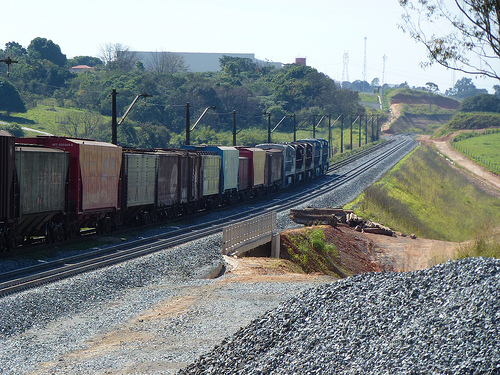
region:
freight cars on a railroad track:
[1, 131, 398, 242]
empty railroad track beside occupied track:
[0, 128, 413, 303]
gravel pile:
[174, 257, 499, 374]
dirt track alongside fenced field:
[428, 126, 498, 190]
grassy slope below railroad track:
[351, 139, 496, 238]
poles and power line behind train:
[4, 89, 330, 232]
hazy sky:
[1, 2, 499, 91]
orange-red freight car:
[19, 134, 121, 239]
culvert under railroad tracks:
[198, 208, 293, 264]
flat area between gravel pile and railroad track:
[1, 231, 498, 374]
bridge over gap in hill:
[210, 207, 285, 267]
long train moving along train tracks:
[0, 126, 332, 256]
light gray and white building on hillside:
[105, 45, 256, 90]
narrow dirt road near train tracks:
[425, 131, 495, 207]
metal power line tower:
[336, 45, 351, 100]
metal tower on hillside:
[376, 47, 386, 92]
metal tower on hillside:
[356, 26, 368, 91]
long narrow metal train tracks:
[0, 132, 420, 302]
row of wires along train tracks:
[1, 51, 385, 178]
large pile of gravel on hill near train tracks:
[158, 246, 497, 373]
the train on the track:
[2, 129, 332, 249]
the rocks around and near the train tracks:
[0, 132, 499, 373]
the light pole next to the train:
[108, 88, 152, 143]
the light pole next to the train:
[183, 102, 217, 144]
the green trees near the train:
[0, 37, 365, 155]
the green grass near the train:
[0, 87, 498, 274]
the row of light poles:
[110, 87, 381, 158]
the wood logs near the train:
[290, 204, 419, 240]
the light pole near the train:
[264, 109, 292, 144]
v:
[347, 111, 364, 150]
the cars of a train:
[0, 134, 336, 253]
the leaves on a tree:
[241, 68, 284, 105]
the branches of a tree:
[457, 0, 496, 70]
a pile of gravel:
[313, 296, 451, 372]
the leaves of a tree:
[11, 51, 40, 85]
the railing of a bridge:
[218, 209, 285, 254]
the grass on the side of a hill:
[406, 181, 443, 221]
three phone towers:
[336, 29, 392, 95]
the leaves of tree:
[113, 59, 138, 89]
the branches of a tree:
[63, 112, 100, 135]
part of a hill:
[388, 154, 401, 181]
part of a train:
[129, 193, 149, 224]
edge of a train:
[171, 163, 179, 180]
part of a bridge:
[243, 245, 252, 256]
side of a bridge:
[234, 193, 254, 251]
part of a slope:
[397, 168, 412, 174]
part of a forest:
[248, 80, 258, 92]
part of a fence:
[227, 110, 231, 115]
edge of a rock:
[331, 299, 338, 324]